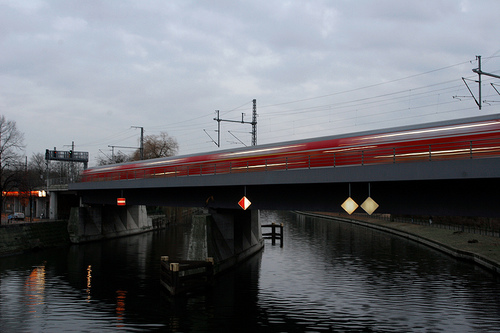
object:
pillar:
[150, 204, 266, 298]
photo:
[0, 0, 499, 333]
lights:
[17, 263, 130, 330]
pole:
[458, 55, 500, 111]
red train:
[81, 110, 500, 183]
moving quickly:
[74, 113, 499, 182]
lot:
[3, 210, 35, 225]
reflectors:
[340, 196, 380, 216]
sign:
[116, 197, 127, 206]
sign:
[234, 192, 260, 210]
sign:
[341, 196, 360, 216]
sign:
[359, 196, 380, 214]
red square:
[117, 198, 126, 207]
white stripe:
[116, 200, 126, 203]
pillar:
[66, 196, 167, 244]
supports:
[68, 190, 265, 296]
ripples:
[238, 289, 345, 326]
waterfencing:
[261, 222, 284, 248]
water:
[1, 211, 500, 333]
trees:
[97, 130, 182, 164]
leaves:
[0, 112, 27, 151]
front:
[0, 146, 81, 214]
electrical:
[253, 56, 479, 144]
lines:
[253, 57, 478, 145]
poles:
[212, 109, 222, 149]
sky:
[0, 0, 499, 170]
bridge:
[34, 138, 499, 300]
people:
[6, 212, 15, 223]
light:
[44, 149, 88, 162]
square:
[115, 197, 125, 206]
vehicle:
[12, 212, 27, 220]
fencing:
[261, 221, 284, 248]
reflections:
[16, 266, 132, 325]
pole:
[251, 98, 258, 145]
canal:
[0, 207, 499, 332]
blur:
[256, 137, 389, 163]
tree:
[0, 112, 27, 191]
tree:
[27, 151, 47, 185]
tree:
[50, 155, 80, 185]